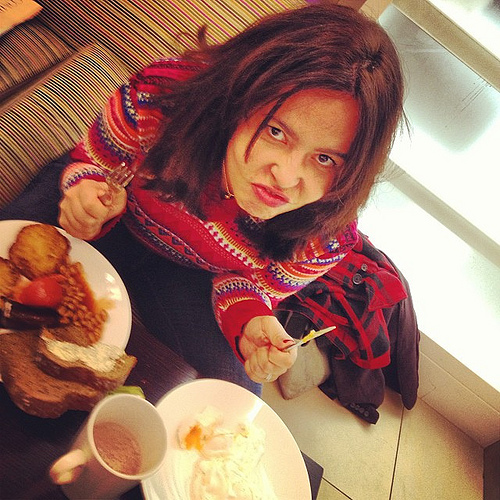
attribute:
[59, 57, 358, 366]
sweater — red, patterned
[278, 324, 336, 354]
knife — silver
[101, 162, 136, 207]
fork — silver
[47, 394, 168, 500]
mug — white, beige, for coffee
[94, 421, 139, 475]
cocoa — hot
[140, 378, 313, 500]
plate — white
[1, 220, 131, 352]
plate — white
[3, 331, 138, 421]
toast — brown, buttered, bread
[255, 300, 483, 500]
floor — tile, white, grouted brown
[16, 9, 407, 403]
woman — preparing to eat, unhappy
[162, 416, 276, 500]
eggs — fried, cooked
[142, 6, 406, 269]
hair — straight, long, brown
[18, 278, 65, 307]
tomato — cooked